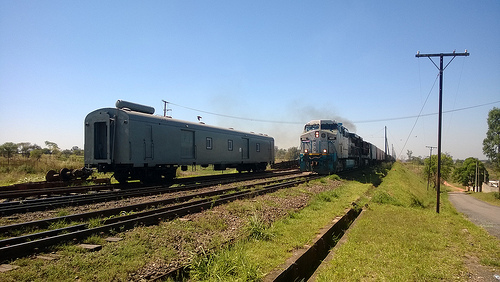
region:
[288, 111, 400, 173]
train traveling on rails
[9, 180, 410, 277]
train rails cover with grass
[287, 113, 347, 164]
the front of the train is white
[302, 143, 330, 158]
headlights of train in front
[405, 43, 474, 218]
pole of electricity near the rails of trains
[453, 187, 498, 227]
road near the rails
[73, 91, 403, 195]
car of train on side of traveling train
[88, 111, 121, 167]
door of car is open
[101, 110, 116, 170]
door of car is on the right side of train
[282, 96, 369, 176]
smoke is coming out a train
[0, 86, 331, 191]
The train on the left.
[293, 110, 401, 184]
The train on the right.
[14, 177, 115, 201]
The tracks in front of the train on the left.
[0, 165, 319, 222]
The tracks in front of the train on the right.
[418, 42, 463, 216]
The T shaped light pole next to the street.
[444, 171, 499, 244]
The street to the right of the trains.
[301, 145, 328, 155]
The two lights on the front of the train on the right.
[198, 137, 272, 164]
The three small windows on the side of the train on the left.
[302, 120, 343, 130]
The two small windows on the front of the train on the left.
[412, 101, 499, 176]
The trees on the right side of the photo.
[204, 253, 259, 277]
Weeds growing by train track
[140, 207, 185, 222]
Tracks used by the train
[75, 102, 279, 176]
Unattached train car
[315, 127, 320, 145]
Headlight on railroad locomotive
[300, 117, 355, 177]
Railroad locomotive pulling train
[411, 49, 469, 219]
Utility pole by side of the road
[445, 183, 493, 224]
Access road for train tracks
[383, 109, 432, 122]
Power wire between utility poles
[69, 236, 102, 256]
Cross tie for railroad tracks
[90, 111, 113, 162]
Access door for train car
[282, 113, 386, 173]
GREY AND BLUE LOCOMOTIVE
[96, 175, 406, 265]
GRASS OVERGROWN ON TRAIN TRACK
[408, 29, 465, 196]
WOODEN POWER POLE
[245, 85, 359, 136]
GREY EXHAUST FROM TRAIN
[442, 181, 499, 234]
PAVED ROAD ON SIDE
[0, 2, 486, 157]
CLEAR BLUE SKY ABOVE TRAIN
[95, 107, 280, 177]
SILVER TRAIN CAR ON TRACK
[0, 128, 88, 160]
TREES OFF IN DISTANCE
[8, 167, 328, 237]
CONCRETE RAILROAD TIES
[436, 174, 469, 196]
CLAY COLORED TRAIL LEADING OFF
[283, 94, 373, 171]
smoke coming from a train engine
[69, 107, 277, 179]
silver train car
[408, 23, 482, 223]
wooden electrical pole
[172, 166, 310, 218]
two sets of train tracks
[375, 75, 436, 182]
electrical guide wires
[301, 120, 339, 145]
lights on a train engine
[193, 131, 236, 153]
two windows on a train car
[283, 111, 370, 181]
silver and blue train car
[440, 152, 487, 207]
several trees next to a road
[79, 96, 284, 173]
a train car parked on train tracks